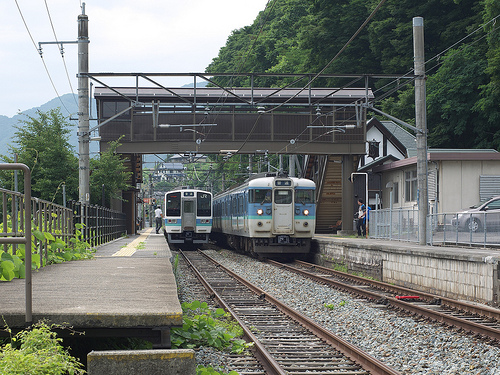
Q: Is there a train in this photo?
A: Yes, there is a train.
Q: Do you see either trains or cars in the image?
A: Yes, there is a train.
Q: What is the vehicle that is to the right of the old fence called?
A: The vehicle is a train.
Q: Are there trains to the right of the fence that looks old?
A: Yes, there is a train to the right of the fence.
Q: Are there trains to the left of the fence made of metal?
A: No, the train is to the right of the fence.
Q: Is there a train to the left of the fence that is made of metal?
A: No, the train is to the right of the fence.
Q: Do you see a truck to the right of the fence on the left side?
A: No, there is a train to the right of the fence.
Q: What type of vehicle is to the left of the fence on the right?
A: The vehicle is a train.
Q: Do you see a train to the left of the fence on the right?
A: Yes, there is a train to the left of the fence.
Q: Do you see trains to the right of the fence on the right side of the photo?
A: No, the train is to the left of the fence.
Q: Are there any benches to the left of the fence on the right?
A: No, there is a train to the left of the fence.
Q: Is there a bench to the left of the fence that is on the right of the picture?
A: No, there is a train to the left of the fence.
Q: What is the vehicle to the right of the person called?
A: The vehicle is a train.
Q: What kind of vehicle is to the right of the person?
A: The vehicle is a train.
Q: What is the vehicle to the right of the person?
A: The vehicle is a train.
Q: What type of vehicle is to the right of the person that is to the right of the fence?
A: The vehicle is a train.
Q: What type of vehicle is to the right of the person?
A: The vehicle is a train.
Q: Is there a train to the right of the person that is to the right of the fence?
A: Yes, there is a train to the right of the person.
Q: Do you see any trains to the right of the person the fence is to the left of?
A: Yes, there is a train to the right of the person.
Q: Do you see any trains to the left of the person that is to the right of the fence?
A: No, the train is to the right of the person.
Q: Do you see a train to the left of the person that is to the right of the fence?
A: No, the train is to the right of the person.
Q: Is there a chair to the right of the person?
A: No, there is a train to the right of the person.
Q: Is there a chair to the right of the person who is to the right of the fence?
A: No, there is a train to the right of the person.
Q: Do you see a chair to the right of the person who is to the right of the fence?
A: No, there is a train to the right of the person.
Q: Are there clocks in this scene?
A: No, there are no clocks.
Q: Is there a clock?
A: No, there are no clocks.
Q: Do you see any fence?
A: Yes, there is a fence.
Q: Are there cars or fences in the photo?
A: Yes, there is a fence.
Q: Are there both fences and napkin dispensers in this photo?
A: No, there is a fence but no napkin dispensers.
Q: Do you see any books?
A: No, there are no books.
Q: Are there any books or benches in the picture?
A: No, there are no books or benches.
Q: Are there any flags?
A: No, there are no flags.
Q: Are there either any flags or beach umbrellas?
A: No, there are no flags or beach umbrellas.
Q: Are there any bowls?
A: No, there are no bowls.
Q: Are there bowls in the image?
A: No, there are no bowls.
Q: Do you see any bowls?
A: No, there are no bowls.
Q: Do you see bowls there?
A: No, there are no bowls.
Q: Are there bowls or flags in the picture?
A: No, there are no bowls or flags.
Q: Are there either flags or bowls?
A: No, there are no bowls or flags.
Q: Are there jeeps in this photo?
A: No, there are no jeeps.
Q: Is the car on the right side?
A: Yes, the car is on the right of the image.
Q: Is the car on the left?
A: No, the car is on the right of the image.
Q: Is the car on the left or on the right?
A: The car is on the right of the image.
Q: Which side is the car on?
A: The car is on the right of the image.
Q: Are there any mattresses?
A: No, there are no mattresses.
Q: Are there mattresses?
A: No, there are no mattresses.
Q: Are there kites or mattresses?
A: No, there are no mattresses or kites.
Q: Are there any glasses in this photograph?
A: No, there are no glasses.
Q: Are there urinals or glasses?
A: No, there are no glasses or urinals.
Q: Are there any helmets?
A: No, there are no helmets.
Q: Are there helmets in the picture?
A: No, there are no helmets.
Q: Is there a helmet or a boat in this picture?
A: No, there are no helmets or boats.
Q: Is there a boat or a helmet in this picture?
A: No, there are no helmets or boats.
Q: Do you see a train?
A: Yes, there is a train.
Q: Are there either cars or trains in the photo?
A: Yes, there is a train.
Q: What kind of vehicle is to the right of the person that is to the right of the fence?
A: The vehicle is a train.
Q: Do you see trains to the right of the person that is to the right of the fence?
A: Yes, there is a train to the right of the person.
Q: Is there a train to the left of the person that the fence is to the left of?
A: No, the train is to the right of the person.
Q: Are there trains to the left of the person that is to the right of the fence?
A: No, the train is to the right of the person.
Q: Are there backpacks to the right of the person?
A: No, there is a train to the right of the person.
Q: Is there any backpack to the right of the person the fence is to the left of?
A: No, there is a train to the right of the person.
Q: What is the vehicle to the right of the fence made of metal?
A: The vehicle is a train.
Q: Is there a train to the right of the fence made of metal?
A: Yes, there is a train to the right of the fence.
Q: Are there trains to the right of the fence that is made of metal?
A: Yes, there is a train to the right of the fence.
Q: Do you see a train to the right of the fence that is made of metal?
A: Yes, there is a train to the right of the fence.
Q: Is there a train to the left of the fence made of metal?
A: No, the train is to the right of the fence.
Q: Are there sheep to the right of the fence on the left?
A: No, there is a train to the right of the fence.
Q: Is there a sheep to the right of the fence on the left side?
A: No, there is a train to the right of the fence.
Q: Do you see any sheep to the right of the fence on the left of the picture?
A: No, there is a train to the right of the fence.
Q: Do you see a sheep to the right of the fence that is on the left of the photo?
A: No, there is a train to the right of the fence.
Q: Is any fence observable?
A: Yes, there is a fence.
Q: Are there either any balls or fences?
A: Yes, there is a fence.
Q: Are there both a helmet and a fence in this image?
A: No, there is a fence but no helmets.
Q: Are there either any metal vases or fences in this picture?
A: Yes, there is a metal fence.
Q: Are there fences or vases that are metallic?
A: Yes, the fence is metallic.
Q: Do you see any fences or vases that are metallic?
A: Yes, the fence is metallic.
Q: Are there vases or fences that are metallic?
A: Yes, the fence is metallic.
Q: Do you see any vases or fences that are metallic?
A: Yes, the fence is metallic.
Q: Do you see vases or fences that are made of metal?
A: Yes, the fence is made of metal.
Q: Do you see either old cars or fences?
A: Yes, there is an old fence.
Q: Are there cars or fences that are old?
A: Yes, the fence is old.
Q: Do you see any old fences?
A: Yes, there is an old fence.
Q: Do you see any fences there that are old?
A: Yes, there is a fence that is old.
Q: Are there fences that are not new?
A: Yes, there is a old fence.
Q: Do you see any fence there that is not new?
A: Yes, there is a old fence.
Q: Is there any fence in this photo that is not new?
A: Yes, there is a old fence.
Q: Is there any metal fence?
A: Yes, there is a fence that is made of metal.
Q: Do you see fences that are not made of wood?
A: Yes, there is a fence that is made of metal.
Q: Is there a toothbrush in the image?
A: No, there are no toothbrushes.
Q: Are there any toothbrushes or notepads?
A: No, there are no toothbrushes or notepads.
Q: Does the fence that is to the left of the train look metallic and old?
A: Yes, the fence is metallic and old.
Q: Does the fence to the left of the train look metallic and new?
A: No, the fence is metallic but old.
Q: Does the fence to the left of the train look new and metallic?
A: No, the fence is metallic but old.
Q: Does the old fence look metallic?
A: Yes, the fence is metallic.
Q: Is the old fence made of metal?
A: Yes, the fence is made of metal.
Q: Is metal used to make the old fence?
A: Yes, the fence is made of metal.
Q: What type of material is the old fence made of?
A: The fence is made of metal.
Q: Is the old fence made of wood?
A: No, the fence is made of metal.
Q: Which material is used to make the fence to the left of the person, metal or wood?
A: The fence is made of metal.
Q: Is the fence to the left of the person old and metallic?
A: Yes, the fence is old and metallic.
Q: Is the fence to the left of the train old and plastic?
A: No, the fence is old but metallic.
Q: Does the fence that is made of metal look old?
A: Yes, the fence is old.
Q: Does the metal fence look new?
A: No, the fence is old.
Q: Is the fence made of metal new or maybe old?
A: The fence is old.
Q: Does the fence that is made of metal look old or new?
A: The fence is old.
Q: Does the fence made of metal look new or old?
A: The fence is old.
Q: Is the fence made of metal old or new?
A: The fence is old.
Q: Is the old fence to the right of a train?
A: No, the fence is to the left of a train.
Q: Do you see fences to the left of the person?
A: Yes, there is a fence to the left of the person.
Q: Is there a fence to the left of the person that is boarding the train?
A: Yes, there is a fence to the left of the person.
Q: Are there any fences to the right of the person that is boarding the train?
A: No, the fence is to the left of the person.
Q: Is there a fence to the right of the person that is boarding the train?
A: No, the fence is to the left of the person.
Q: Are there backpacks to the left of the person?
A: No, there is a fence to the left of the person.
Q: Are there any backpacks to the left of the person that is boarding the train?
A: No, there is a fence to the left of the person.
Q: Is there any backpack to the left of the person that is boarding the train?
A: No, there is a fence to the left of the person.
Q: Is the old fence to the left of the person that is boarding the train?
A: Yes, the fence is to the left of the person.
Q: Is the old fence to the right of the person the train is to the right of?
A: No, the fence is to the left of the person.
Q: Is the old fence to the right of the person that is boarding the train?
A: No, the fence is to the left of the person.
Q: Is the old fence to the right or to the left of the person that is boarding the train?
A: The fence is to the left of the person.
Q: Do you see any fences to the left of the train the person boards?
A: Yes, there is a fence to the left of the train.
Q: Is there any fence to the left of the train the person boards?
A: Yes, there is a fence to the left of the train.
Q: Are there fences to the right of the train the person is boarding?
A: No, the fence is to the left of the train.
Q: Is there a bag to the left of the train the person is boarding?
A: No, there is a fence to the left of the train.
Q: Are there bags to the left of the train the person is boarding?
A: No, there is a fence to the left of the train.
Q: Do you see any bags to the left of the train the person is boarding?
A: No, there is a fence to the left of the train.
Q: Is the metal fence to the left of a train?
A: Yes, the fence is to the left of a train.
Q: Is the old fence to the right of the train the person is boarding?
A: No, the fence is to the left of the train.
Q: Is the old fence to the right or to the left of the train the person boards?
A: The fence is to the left of the train.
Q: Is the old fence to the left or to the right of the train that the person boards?
A: The fence is to the left of the train.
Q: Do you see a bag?
A: No, there are no bags.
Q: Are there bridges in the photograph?
A: Yes, there is a bridge.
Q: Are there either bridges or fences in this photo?
A: Yes, there is a bridge.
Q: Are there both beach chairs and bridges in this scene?
A: No, there is a bridge but no beach chairs.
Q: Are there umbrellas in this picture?
A: No, there are no umbrellas.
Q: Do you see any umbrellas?
A: No, there are no umbrellas.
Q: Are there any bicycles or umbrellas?
A: No, there are no umbrellas or bicycles.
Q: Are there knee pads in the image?
A: No, there are no knee pads.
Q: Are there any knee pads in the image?
A: No, there are no knee pads.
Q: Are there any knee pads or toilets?
A: No, there are no knee pads or toilets.